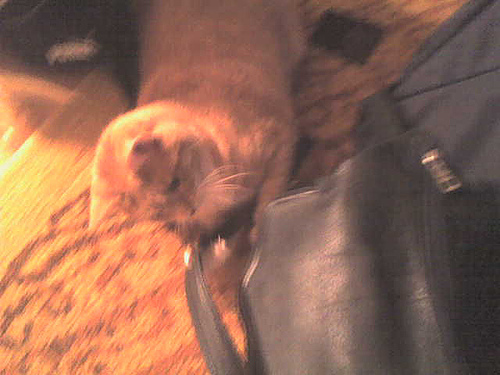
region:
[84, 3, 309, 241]
fat orange cat laying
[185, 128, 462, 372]
leather black purse with gold zipper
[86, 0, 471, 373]
cat playing with a purse strap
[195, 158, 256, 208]
white whiskers of a cat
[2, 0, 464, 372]
area rug with patterns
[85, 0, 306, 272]
cat laying on the floor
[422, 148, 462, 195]
shiny rectangular zipper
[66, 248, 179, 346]
part of an object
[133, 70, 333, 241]
part of an object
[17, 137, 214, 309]
part of an object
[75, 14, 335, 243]
Small cat on the floor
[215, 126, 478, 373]
Black purse on the floor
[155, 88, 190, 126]
Patch of orange hair on cat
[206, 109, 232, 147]
Patch of orange hair on cat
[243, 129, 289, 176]
Patch of orange hair on cat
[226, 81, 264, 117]
Patch of orange hair on cat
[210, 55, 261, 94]
Patch of orange hair on cat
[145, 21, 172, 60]
Patch of orange hair on cat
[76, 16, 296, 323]
a cat on the floor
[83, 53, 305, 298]
a cat is inside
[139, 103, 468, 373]
a purse on the floor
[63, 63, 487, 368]
a cat and a black purse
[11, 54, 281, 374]
a rug on the floor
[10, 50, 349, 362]
a cat on a rug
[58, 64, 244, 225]
a cat with whiskers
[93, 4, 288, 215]
Cat laying on the floor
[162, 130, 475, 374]
leather bag on the floor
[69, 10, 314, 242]
brown cat on the floor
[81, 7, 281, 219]
Cat laying on the carpet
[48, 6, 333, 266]
Cat laying on the carpet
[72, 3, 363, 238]
Cat laying on the carpet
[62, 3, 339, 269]
Cat laying on the carpet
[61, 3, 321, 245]
Cat laying on the carpet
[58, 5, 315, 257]
Cat laying on the carpet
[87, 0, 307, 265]
orange cat playing with a strap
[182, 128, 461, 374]
black leather purse on the floor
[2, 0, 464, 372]
orange area rug